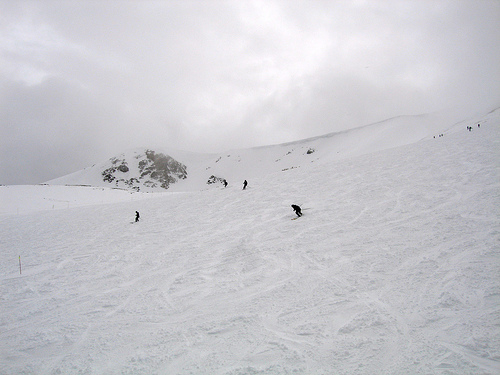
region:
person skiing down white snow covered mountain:
[129, 202, 151, 226]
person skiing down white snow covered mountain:
[285, 200, 310, 225]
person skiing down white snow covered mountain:
[233, 177, 253, 195]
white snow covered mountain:
[8, 250, 220, 373]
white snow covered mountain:
[196, 239, 489, 361]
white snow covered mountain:
[6, 192, 123, 301]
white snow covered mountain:
[331, 140, 484, 282]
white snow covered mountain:
[116, 151, 197, 198]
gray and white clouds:
[9, 12, 210, 144]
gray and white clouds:
[191, 7, 474, 102]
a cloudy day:
[20, 3, 495, 205]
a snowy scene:
[16, 108, 482, 363]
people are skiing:
[27, 117, 478, 353]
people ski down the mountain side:
[20, 114, 491, 373]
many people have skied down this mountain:
[63, 121, 494, 361]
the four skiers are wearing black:
[131, 159, 327, 255]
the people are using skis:
[118, 171, 319, 258]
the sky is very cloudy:
[42, 23, 491, 194]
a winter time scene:
[36, 48, 453, 373]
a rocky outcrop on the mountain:
[80, 145, 202, 194]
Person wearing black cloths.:
[285, 196, 306, 224]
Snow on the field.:
[0, 151, 499, 373]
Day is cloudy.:
[5, 7, 490, 142]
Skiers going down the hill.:
[119, 166, 313, 238]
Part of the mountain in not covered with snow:
[96, 147, 200, 195]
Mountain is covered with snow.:
[313, 89, 459, 148]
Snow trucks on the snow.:
[1, 236, 498, 373]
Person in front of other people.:
[126, 200, 146, 227]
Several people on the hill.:
[425, 115, 488, 148]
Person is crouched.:
[281, 198, 308, 225]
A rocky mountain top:
[76, 142, 197, 193]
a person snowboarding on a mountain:
[123, 205, 144, 227]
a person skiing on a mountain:
[285, 191, 312, 228]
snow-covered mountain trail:
[125, 240, 355, 340]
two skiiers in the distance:
[210, 168, 256, 198]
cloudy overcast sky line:
[50, 38, 400, 98]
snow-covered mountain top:
[36, 135, 196, 196]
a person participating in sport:
[280, 196, 311, 224]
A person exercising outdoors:
[126, 205, 144, 226]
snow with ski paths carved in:
[353, 216, 498, 370]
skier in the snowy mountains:
[275, 198, 310, 224]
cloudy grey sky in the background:
[14, 14, 467, 92]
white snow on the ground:
[38, 270, 450, 346]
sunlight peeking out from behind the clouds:
[280, 41, 327, 77]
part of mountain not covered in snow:
[147, 155, 185, 176]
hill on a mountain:
[47, 147, 209, 195]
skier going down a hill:
[127, 205, 146, 231]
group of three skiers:
[460, 123, 487, 139]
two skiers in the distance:
[213, 177, 264, 195]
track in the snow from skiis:
[372, 303, 421, 353]